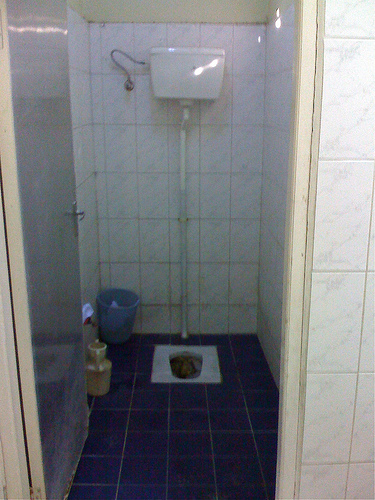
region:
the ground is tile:
[138, 398, 215, 477]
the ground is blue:
[140, 433, 181, 492]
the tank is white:
[140, 44, 232, 108]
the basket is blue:
[91, 262, 147, 358]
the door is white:
[23, 2, 108, 473]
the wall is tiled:
[121, 128, 174, 219]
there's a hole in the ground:
[145, 327, 232, 398]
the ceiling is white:
[158, 5, 198, 20]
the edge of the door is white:
[275, 141, 317, 278]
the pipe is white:
[163, 102, 218, 343]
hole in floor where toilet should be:
[146, 343, 233, 394]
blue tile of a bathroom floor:
[109, 396, 259, 485]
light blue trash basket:
[94, 283, 150, 346]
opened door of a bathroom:
[6, 133, 97, 498]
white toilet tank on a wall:
[142, 38, 228, 112]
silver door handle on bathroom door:
[70, 202, 89, 241]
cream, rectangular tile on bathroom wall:
[311, 269, 366, 375]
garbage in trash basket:
[101, 295, 122, 307]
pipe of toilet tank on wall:
[172, 102, 202, 344]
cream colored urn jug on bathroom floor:
[77, 333, 121, 397]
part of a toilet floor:
[222, 392, 255, 422]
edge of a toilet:
[207, 359, 219, 378]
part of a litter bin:
[114, 317, 125, 330]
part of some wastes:
[175, 354, 194, 380]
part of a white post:
[180, 204, 190, 309]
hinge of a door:
[29, 487, 40, 498]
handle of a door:
[77, 211, 85, 226]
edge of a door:
[13, 252, 32, 315]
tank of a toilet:
[169, 62, 211, 81]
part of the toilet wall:
[210, 275, 240, 317]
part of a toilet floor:
[188, 401, 246, 443]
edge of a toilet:
[205, 354, 216, 384]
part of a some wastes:
[179, 361, 194, 375]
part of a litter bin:
[111, 310, 132, 338]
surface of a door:
[30, 350, 78, 405]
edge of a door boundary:
[274, 421, 284, 479]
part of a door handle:
[71, 207, 88, 226]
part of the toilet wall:
[201, 233, 241, 281]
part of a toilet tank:
[174, 79, 208, 111]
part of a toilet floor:
[200, 406, 238, 432]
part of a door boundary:
[275, 460, 285, 493]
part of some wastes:
[179, 363, 195, 375]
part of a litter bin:
[105, 287, 135, 326]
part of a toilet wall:
[186, 237, 228, 309]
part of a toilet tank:
[161, 63, 196, 91]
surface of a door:
[28, 214, 70, 257]